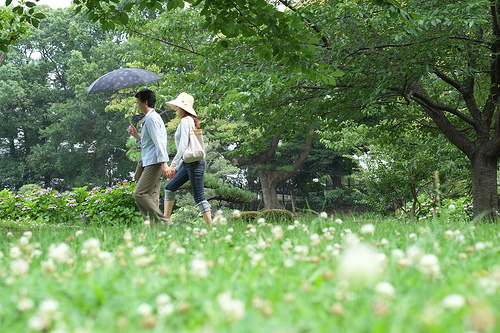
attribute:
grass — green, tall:
[23, 232, 467, 323]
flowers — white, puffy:
[333, 226, 392, 298]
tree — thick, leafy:
[329, 24, 499, 213]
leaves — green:
[380, 44, 423, 77]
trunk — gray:
[465, 147, 500, 241]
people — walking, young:
[130, 60, 221, 213]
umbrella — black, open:
[90, 57, 186, 100]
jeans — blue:
[169, 152, 210, 207]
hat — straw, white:
[172, 95, 197, 112]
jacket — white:
[136, 117, 175, 168]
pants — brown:
[131, 167, 166, 228]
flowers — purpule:
[36, 183, 64, 212]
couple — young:
[104, 85, 218, 228]